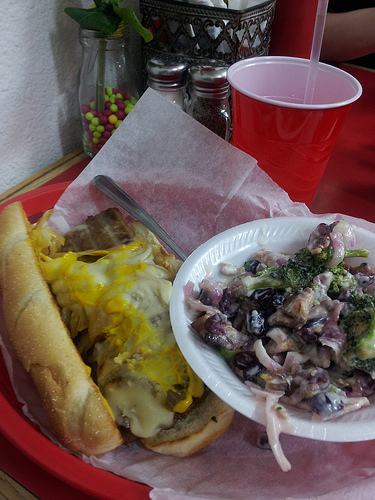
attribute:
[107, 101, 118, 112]
object — Green, yellow, and red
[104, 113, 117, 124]
object — Green, yellow, and red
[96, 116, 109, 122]
object — Green, yellow, and red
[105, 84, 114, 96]
object — Green, yellow, and red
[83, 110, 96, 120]
object — Green, yellow, and red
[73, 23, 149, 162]
vase — glass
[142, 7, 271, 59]
holder — for Napkin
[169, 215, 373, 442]
plate — white, foam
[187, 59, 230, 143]
pepper — Black, in shaker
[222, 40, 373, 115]
cup — Red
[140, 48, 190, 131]
shaker — salt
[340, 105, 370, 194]
table — Red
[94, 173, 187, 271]
utensil — Silver , for eating 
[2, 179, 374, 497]
plate — red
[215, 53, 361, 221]
cup — red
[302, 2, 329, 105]
straw — Clear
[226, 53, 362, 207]
cup — one, red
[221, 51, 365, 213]
container — Red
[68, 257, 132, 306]
mustard — Yellow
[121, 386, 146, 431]
cheese — melted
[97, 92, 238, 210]
paper — White, wrapper